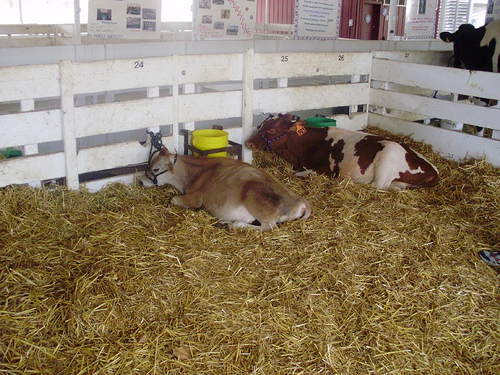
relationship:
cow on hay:
[139, 142, 313, 232] [1, 125, 499, 374]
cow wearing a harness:
[139, 142, 313, 232] [145, 130, 179, 187]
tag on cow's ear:
[295, 123, 307, 137] [288, 119, 309, 133]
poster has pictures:
[88, 0, 161, 42] [97, 7, 156, 33]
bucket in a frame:
[191, 128, 228, 158] [180, 125, 243, 160]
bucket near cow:
[305, 116, 336, 129] [245, 112, 440, 192]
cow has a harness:
[139, 142, 313, 232] [145, 130, 179, 187]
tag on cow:
[295, 123, 307, 137] [245, 112, 440, 192]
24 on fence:
[134, 59, 145, 69] [1, 26, 500, 194]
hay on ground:
[1, 125, 499, 374] [0, 123, 499, 374]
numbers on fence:
[133, 51, 411, 68] [1, 26, 500, 194]